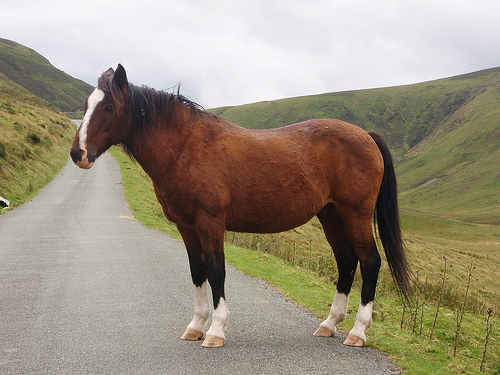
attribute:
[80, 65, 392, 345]
horse — brown, white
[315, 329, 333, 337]
hoof — back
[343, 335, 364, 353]
hoof — back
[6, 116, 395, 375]
concrete — gray, paved, long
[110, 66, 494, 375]
grass — green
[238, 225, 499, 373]
fence — wire, long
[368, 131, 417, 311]
tail — black, long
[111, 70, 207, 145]
mane — black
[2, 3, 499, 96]
sky — gray, cloudy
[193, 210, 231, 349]
leg — brown, black, beige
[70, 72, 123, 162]
face — long